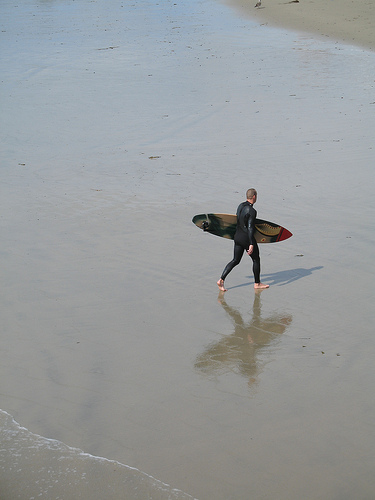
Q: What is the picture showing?
A: It is showing a shore.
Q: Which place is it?
A: It is a shore.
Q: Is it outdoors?
A: Yes, it is outdoors.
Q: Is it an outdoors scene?
A: Yes, it is outdoors.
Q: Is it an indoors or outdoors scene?
A: It is outdoors.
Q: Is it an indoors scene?
A: No, it is outdoors.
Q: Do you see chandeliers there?
A: No, there are no chandeliers.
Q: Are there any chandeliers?
A: No, there are no chandeliers.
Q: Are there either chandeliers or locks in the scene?
A: No, there are no chandeliers or locks.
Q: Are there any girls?
A: No, there are no girls.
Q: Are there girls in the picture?
A: No, there are no girls.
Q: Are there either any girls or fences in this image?
A: No, there are no girls or fences.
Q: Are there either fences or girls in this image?
A: No, there are no girls or fences.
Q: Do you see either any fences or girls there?
A: No, there are no girls or fences.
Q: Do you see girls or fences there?
A: No, there are no girls or fences.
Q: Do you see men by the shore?
A: Yes, there is a man by the shore.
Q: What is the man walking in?
A: The man is walking in the water.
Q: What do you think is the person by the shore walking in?
A: The man is walking in the water.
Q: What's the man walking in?
A: The man is walking in the water.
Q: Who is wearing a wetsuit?
A: The man is wearing a wetsuit.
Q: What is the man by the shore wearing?
A: The man is wearing a wetsuit.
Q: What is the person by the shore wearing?
A: The man is wearing a wetsuit.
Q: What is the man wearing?
A: The man is wearing a wetsuit.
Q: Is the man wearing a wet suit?
A: Yes, the man is wearing a wet suit.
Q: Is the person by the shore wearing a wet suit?
A: Yes, the man is wearing a wet suit.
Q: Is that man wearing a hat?
A: No, the man is wearing a wet suit.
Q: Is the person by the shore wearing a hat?
A: No, the man is wearing a wet suit.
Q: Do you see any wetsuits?
A: Yes, there is a wetsuit.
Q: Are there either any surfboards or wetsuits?
A: Yes, there is a wetsuit.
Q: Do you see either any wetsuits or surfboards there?
A: Yes, there is a wetsuit.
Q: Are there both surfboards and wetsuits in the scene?
A: Yes, there are both a wetsuit and a surfboard.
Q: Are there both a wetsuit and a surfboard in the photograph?
A: Yes, there are both a wetsuit and a surfboard.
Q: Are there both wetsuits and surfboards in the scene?
A: Yes, there are both a wetsuit and a surfboard.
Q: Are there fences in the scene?
A: No, there are no fences.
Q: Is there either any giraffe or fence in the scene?
A: No, there are no fences or giraffes.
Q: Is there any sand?
A: Yes, there is sand.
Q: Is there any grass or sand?
A: Yes, there is sand.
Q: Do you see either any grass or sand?
A: Yes, there is sand.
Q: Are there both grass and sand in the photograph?
A: No, there is sand but no grass.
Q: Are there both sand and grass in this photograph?
A: No, there is sand but no grass.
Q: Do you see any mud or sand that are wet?
A: Yes, the sand is wet.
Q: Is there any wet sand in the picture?
A: Yes, there is wet sand.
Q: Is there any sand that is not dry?
A: Yes, there is wet sand.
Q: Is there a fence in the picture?
A: No, there are no fences.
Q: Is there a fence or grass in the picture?
A: No, there are no fences or grass.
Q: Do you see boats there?
A: No, there are no boats.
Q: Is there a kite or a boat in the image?
A: No, there are no boats or kites.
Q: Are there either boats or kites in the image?
A: No, there are no boats or kites.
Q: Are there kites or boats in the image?
A: No, there are no boats or kites.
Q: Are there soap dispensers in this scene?
A: No, there are no soap dispensers.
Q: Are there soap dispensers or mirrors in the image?
A: No, there are no soap dispensers or mirrors.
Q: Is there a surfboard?
A: Yes, there is a surfboard.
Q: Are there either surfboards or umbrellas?
A: Yes, there is a surfboard.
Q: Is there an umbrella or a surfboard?
A: Yes, there is a surfboard.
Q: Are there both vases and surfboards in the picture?
A: No, there is a surfboard but no vases.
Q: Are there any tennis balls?
A: No, there are no tennis balls.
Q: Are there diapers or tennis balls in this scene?
A: No, there are no tennis balls or diapers.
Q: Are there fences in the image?
A: No, there are no fences.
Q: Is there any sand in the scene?
A: Yes, there is sand.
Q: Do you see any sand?
A: Yes, there is sand.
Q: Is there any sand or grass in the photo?
A: Yes, there is sand.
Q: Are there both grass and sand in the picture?
A: No, there is sand but no grass.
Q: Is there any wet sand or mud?
A: Yes, there is wet sand.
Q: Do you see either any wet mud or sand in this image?
A: Yes, there is wet sand.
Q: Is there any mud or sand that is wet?
A: Yes, the sand is wet.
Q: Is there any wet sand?
A: Yes, there is wet sand.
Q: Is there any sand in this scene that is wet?
A: Yes, there is sand that is wet.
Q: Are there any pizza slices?
A: No, there are no pizza slices.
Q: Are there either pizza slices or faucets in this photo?
A: No, there are no pizza slices or faucets.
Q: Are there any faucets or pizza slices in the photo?
A: No, there are no pizza slices or faucets.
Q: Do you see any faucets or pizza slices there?
A: No, there are no pizza slices or faucets.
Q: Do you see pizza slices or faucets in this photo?
A: No, there are no pizza slices or faucets.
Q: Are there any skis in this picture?
A: No, there are no skis.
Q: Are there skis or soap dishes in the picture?
A: No, there are no skis or soap dishes.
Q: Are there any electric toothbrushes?
A: No, there are no electric toothbrushes.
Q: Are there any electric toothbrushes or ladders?
A: No, there are no electric toothbrushes or ladders.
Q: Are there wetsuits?
A: Yes, there is a wetsuit.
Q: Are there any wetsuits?
A: Yes, there is a wetsuit.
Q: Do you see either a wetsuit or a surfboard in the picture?
A: Yes, there is a wetsuit.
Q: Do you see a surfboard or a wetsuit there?
A: Yes, there is a wetsuit.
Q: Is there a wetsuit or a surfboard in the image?
A: Yes, there is a wetsuit.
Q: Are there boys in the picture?
A: No, there are no boys.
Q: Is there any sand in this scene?
A: Yes, there is sand.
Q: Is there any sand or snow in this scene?
A: Yes, there is sand.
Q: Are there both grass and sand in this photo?
A: No, there is sand but no grass.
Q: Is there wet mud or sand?
A: Yes, there is wet sand.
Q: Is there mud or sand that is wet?
A: Yes, the sand is wet.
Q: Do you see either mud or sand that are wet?
A: Yes, the sand is wet.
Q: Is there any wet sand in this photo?
A: Yes, there is wet sand.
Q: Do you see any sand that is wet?
A: Yes, there is sand that is wet.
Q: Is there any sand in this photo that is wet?
A: Yes, there is sand that is wet.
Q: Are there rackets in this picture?
A: No, there are no rackets.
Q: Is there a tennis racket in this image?
A: No, there are no rackets.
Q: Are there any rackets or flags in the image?
A: No, there are no rackets or flags.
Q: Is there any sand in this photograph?
A: Yes, there is sand.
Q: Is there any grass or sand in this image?
A: Yes, there is sand.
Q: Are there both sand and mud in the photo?
A: No, there is sand but no mud.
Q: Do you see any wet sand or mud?
A: Yes, there is wet sand.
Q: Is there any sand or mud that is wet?
A: Yes, the sand is wet.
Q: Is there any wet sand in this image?
A: Yes, there is wet sand.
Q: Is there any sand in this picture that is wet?
A: Yes, there is wet sand.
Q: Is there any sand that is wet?
A: Yes, there is sand that is wet.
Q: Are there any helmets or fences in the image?
A: No, there are no fences or helmets.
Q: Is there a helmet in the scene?
A: No, there are no helmets.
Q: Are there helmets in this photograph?
A: No, there are no helmets.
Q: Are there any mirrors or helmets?
A: No, there are no helmets or mirrors.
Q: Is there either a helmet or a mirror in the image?
A: No, there are no helmets or mirrors.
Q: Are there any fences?
A: No, there are no fences.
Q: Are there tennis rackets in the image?
A: No, there are no tennis rackets.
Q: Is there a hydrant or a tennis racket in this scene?
A: No, there are no rackets or fire hydrants.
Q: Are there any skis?
A: No, there are no skis.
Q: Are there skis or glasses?
A: No, there are no skis or glasses.